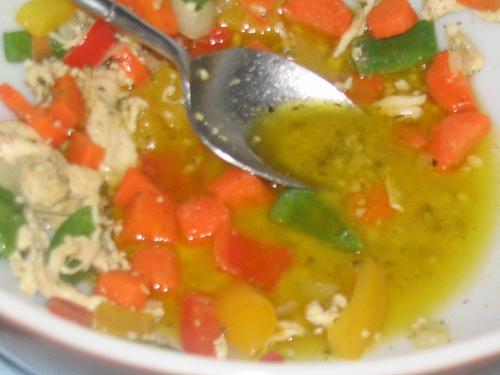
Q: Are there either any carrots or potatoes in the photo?
A: Yes, there is a carrot.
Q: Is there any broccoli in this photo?
A: No, there is no broccoli.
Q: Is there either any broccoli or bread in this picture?
A: No, there are no broccoli or breads.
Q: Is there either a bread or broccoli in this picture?
A: No, there are no broccoli or breads.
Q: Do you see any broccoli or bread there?
A: No, there are no broccoli or breads.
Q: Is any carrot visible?
A: Yes, there is a carrot.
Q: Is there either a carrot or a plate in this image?
A: Yes, there is a carrot.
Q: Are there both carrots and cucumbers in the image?
A: No, there is a carrot but no cucumbers.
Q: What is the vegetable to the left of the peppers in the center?
A: The vegetable is a carrot.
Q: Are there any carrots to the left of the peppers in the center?
A: Yes, there is a carrot to the left of the peppers.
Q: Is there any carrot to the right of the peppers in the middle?
A: No, the carrot is to the left of the peppers.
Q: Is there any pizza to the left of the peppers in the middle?
A: No, there is a carrot to the left of the peppers.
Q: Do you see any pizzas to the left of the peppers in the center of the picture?
A: No, there is a carrot to the left of the peppers.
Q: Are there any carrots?
A: Yes, there is a carrot.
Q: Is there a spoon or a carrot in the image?
A: Yes, there is a carrot.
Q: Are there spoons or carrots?
A: Yes, there is a carrot.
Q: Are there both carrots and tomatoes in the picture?
A: No, there is a carrot but no tomatoes.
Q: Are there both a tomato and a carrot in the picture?
A: No, there is a carrot but no tomatoes.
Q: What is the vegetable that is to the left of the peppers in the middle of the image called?
A: The vegetable is a carrot.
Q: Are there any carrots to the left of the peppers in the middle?
A: Yes, there is a carrot to the left of the peppers.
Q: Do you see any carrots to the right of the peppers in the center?
A: No, the carrot is to the left of the peppers.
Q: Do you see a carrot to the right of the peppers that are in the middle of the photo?
A: No, the carrot is to the left of the peppers.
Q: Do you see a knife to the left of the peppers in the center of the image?
A: No, there is a carrot to the left of the peppers.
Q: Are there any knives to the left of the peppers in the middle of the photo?
A: No, there is a carrot to the left of the peppers.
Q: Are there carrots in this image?
A: Yes, there is a carrot.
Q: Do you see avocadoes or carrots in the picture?
A: Yes, there is a carrot.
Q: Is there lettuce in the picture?
A: No, there is no lettuce.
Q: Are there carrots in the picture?
A: Yes, there is a carrot.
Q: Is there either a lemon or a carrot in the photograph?
A: Yes, there is a carrot.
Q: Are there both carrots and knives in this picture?
A: No, there is a carrot but no knives.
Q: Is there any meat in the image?
A: Yes, there is meat.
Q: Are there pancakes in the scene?
A: No, there are no pancakes.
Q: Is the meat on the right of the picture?
A: Yes, the meat is on the right of the image.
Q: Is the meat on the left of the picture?
A: No, the meat is on the right of the image.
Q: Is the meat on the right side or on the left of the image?
A: The meat is on the right of the image.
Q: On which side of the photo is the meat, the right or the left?
A: The meat is on the right of the image.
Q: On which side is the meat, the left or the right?
A: The meat is on the right of the image.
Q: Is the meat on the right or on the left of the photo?
A: The meat is on the right of the image.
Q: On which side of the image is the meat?
A: The meat is on the right of the image.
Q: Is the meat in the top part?
A: Yes, the meat is in the top of the image.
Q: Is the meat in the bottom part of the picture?
A: No, the meat is in the top of the image.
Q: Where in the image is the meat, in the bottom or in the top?
A: The meat is in the top of the image.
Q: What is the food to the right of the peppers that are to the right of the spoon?
A: The food is meat.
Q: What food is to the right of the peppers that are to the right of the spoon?
A: The food is meat.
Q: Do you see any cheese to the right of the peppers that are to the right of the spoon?
A: No, there is meat to the right of the peppers.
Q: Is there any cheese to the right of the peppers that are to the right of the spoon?
A: No, there is meat to the right of the peppers.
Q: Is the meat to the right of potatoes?
A: No, the meat is to the right of the peppers.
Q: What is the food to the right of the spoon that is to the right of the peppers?
A: The food is meat.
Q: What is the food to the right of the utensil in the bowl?
A: The food is meat.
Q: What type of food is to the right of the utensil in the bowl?
A: The food is meat.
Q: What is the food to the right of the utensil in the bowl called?
A: The food is meat.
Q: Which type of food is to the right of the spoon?
A: The food is meat.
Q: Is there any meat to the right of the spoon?
A: Yes, there is meat to the right of the spoon.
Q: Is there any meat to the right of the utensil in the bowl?
A: Yes, there is meat to the right of the spoon.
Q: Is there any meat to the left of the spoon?
A: No, the meat is to the right of the spoon.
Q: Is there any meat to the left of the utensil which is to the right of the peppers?
A: No, the meat is to the right of the spoon.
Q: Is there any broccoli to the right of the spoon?
A: No, there is meat to the right of the spoon.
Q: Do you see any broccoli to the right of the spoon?
A: No, there is meat to the right of the spoon.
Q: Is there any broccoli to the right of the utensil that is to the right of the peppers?
A: No, there is meat to the right of the spoon.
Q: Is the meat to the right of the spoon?
A: Yes, the meat is to the right of the spoon.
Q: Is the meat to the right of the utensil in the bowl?
A: Yes, the meat is to the right of the spoon.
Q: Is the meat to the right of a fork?
A: No, the meat is to the right of the spoon.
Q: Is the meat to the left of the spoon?
A: No, the meat is to the right of the spoon.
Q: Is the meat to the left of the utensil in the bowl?
A: No, the meat is to the right of the spoon.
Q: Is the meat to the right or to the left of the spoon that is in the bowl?
A: The meat is to the right of the spoon.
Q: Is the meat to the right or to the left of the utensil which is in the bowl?
A: The meat is to the right of the spoon.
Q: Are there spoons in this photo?
A: Yes, there is a spoon.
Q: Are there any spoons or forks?
A: Yes, there is a spoon.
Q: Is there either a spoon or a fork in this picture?
A: Yes, there is a spoon.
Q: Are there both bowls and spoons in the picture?
A: Yes, there are both a spoon and a bowl.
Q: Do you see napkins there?
A: No, there are no napkins.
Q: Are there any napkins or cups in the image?
A: No, there are no napkins or cups.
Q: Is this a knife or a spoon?
A: This is a spoon.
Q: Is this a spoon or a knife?
A: This is a spoon.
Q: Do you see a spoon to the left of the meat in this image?
A: Yes, there is a spoon to the left of the meat.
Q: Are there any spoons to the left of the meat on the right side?
A: Yes, there is a spoon to the left of the meat.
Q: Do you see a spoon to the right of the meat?
A: No, the spoon is to the left of the meat.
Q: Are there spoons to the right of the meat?
A: No, the spoon is to the left of the meat.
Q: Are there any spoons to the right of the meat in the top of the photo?
A: No, the spoon is to the left of the meat.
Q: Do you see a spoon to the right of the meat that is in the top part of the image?
A: No, the spoon is to the left of the meat.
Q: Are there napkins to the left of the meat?
A: No, there is a spoon to the left of the meat.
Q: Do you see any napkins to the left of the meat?
A: No, there is a spoon to the left of the meat.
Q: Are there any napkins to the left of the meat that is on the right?
A: No, there is a spoon to the left of the meat.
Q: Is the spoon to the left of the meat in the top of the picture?
A: Yes, the spoon is to the left of the meat.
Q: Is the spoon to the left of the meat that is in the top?
A: Yes, the spoon is to the left of the meat.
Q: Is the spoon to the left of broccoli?
A: No, the spoon is to the left of the meat.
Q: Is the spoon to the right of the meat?
A: No, the spoon is to the left of the meat.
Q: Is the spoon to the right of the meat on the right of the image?
A: No, the spoon is to the left of the meat.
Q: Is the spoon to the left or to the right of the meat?
A: The spoon is to the left of the meat.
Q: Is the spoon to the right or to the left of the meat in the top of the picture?
A: The spoon is to the left of the meat.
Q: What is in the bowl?
A: The spoon is in the bowl.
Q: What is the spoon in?
A: The spoon is in the bowl.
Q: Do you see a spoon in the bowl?
A: Yes, there is a spoon in the bowl.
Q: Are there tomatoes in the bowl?
A: No, there is a spoon in the bowl.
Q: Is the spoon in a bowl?
A: Yes, the spoon is in a bowl.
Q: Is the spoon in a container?
A: No, the spoon is in a bowl.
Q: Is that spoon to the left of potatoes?
A: No, the spoon is to the left of the peppers.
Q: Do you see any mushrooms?
A: No, there are no mushrooms.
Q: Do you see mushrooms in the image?
A: No, there are no mushrooms.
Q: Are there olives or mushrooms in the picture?
A: No, there are no mushrooms or olives.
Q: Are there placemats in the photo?
A: No, there are no placemats.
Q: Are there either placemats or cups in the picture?
A: No, there are no placemats or cups.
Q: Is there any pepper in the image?
A: Yes, there are peppers.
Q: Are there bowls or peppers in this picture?
A: Yes, there are peppers.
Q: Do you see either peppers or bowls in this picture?
A: Yes, there are peppers.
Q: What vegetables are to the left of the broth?
A: The vegetables are peppers.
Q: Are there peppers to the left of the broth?
A: Yes, there are peppers to the left of the broth.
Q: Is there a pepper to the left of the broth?
A: Yes, there are peppers to the left of the broth.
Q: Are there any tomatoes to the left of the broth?
A: No, there are peppers to the left of the broth.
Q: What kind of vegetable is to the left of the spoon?
A: The vegetables are peppers.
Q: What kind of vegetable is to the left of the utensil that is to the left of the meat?
A: The vegetables are peppers.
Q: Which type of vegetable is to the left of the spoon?
A: The vegetables are peppers.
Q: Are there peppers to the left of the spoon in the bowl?
A: Yes, there are peppers to the left of the spoon.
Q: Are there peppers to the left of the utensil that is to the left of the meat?
A: Yes, there are peppers to the left of the spoon.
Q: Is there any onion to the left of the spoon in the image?
A: No, there are peppers to the left of the spoon.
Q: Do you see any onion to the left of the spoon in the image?
A: No, there are peppers to the left of the spoon.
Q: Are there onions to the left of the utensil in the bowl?
A: No, there are peppers to the left of the spoon.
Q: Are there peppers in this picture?
A: Yes, there are peppers.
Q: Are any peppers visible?
A: Yes, there are peppers.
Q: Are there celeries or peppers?
A: Yes, there are peppers.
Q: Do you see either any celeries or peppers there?
A: Yes, there are peppers.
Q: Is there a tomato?
A: No, there are no tomatoes.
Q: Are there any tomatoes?
A: No, there are no tomatoes.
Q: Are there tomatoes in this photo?
A: No, there are no tomatoes.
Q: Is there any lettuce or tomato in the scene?
A: No, there are no tomatoes or lettuce.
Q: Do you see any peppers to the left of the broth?
A: Yes, there are peppers to the left of the broth.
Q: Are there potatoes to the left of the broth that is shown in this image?
A: No, there are peppers to the left of the broth.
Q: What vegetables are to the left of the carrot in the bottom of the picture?
A: The vegetables are peppers.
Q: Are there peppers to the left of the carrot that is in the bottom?
A: Yes, there are peppers to the left of the carrot.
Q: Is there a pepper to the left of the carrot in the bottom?
A: Yes, there are peppers to the left of the carrot.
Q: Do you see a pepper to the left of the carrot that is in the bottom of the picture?
A: Yes, there are peppers to the left of the carrot.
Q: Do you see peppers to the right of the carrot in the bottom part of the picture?
A: No, the peppers are to the left of the carrot.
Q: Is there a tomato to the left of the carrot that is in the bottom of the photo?
A: No, there are peppers to the left of the carrot.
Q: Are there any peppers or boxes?
A: Yes, there are peppers.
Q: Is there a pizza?
A: No, there are no pizzas.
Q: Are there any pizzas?
A: No, there are no pizzas.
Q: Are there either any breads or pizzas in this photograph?
A: No, there are no pizzas or breads.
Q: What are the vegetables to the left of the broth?
A: The vegetables are peppers.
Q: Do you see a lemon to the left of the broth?
A: No, there are peppers to the left of the broth.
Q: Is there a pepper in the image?
A: Yes, there are peppers.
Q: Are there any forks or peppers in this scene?
A: Yes, there are peppers.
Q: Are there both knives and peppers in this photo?
A: No, there are peppers but no knives.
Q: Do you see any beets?
A: No, there are no beets.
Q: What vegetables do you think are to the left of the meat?
A: The vegetables are peppers.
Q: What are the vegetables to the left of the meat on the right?
A: The vegetables are peppers.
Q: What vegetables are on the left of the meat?
A: The vegetables are peppers.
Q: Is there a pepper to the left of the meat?
A: Yes, there are peppers to the left of the meat.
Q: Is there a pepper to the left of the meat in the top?
A: Yes, there are peppers to the left of the meat.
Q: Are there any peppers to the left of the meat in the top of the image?
A: Yes, there are peppers to the left of the meat.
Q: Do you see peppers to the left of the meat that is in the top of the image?
A: Yes, there are peppers to the left of the meat.